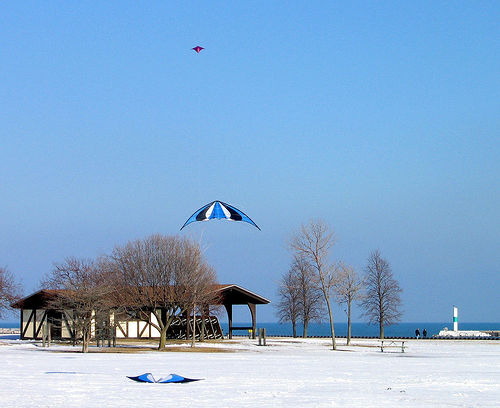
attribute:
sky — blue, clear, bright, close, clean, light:
[99, 62, 390, 165]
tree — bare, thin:
[278, 206, 408, 344]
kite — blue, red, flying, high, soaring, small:
[184, 30, 217, 69]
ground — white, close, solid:
[236, 341, 390, 394]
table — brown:
[365, 318, 416, 363]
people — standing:
[368, 312, 444, 349]